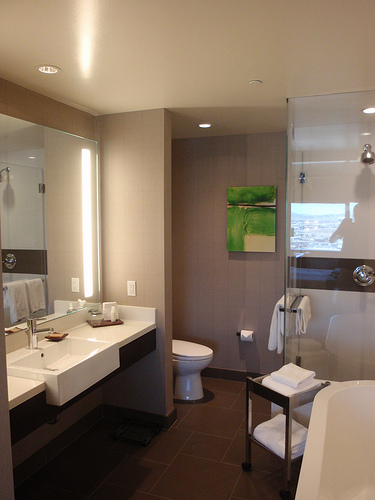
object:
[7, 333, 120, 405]
sink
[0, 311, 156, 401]
counter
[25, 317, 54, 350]
faucet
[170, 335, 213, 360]
toilet seat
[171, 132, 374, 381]
wall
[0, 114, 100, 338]
mirror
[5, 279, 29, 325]
towels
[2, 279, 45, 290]
rod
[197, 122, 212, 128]
light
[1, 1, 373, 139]
ceiling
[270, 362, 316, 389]
towels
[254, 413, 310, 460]
towels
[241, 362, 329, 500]
rack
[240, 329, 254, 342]
toilet paper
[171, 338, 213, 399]
toilet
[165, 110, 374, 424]
alcove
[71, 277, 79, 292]
electrical outlet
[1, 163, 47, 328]
shower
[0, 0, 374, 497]
bathroom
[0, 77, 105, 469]
wall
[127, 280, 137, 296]
eletrical outlet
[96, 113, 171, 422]
wall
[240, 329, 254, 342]
paper roll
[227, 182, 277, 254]
picture